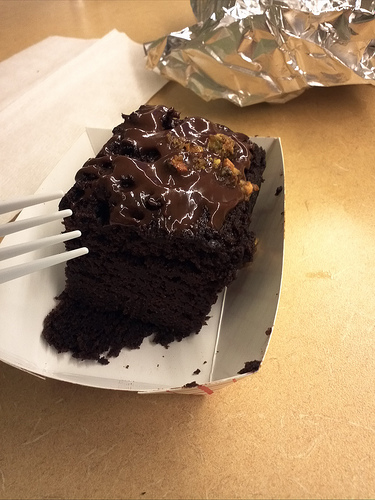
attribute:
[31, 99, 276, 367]
cake — chocolate, black forest, thick, here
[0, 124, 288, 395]
tray — white, small, paper, made of paper, dessert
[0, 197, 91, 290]
fork — white, plastic, of fork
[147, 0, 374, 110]
tinfoil — crumpled, aluminum, shiny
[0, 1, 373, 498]
counter top — beige, tan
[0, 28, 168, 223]
napkin — white, unused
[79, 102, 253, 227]
chocolate icing — gooey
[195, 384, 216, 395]
stripe — red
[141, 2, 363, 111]
paper — foil